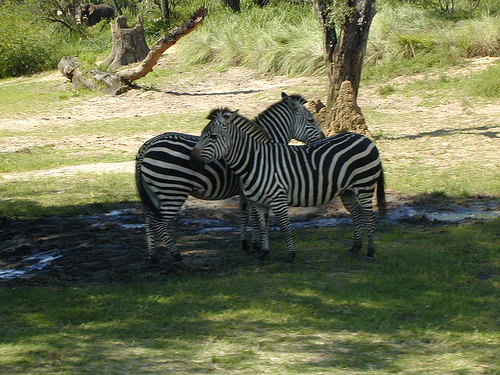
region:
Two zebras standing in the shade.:
[26, 45, 463, 345]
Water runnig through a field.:
[6, 130, 495, 312]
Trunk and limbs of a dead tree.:
[51, 8, 206, 102]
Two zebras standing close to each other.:
[118, 62, 403, 292]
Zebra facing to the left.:
[185, 100, 397, 265]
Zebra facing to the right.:
[135, 82, 322, 261]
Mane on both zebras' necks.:
[190, 91, 285, 176]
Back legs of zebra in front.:
[334, 127, 386, 272]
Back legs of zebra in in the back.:
[132, 148, 186, 277]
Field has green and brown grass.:
[16, 60, 483, 372]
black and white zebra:
[192, 109, 389, 259]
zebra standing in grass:
[131, 94, 324, 272]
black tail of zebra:
[378, 160, 388, 222]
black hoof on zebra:
[368, 249, 375, 258]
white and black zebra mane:
[206, 107, 271, 146]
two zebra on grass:
[135, 90, 390, 265]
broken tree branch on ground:
[48, 9, 205, 92]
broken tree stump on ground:
[107, 15, 150, 62]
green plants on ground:
[2, 3, 78, 75]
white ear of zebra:
[220, 112, 233, 123]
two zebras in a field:
[124, 85, 399, 285]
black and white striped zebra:
[188, 103, 391, 265]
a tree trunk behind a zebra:
[311, 0, 374, 145]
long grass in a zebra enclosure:
[181, 3, 491, 85]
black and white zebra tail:
[131, 151, 165, 222]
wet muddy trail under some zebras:
[1, 198, 498, 285]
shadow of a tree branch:
[122, 70, 287, 99]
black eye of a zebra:
[208, 130, 221, 141]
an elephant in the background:
[73, 3, 118, 35]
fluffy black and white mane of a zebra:
[204, 107, 274, 145]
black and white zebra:
[259, 96, 319, 128]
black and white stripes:
[298, 170, 343, 203]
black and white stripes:
[154, 141, 200, 195]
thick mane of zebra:
[241, 111, 253, 127]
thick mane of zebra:
[254, 99, 284, 116]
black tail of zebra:
[370, 139, 387, 226]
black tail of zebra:
[122, 171, 159, 228]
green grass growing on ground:
[162, 286, 303, 366]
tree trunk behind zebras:
[330, 18, 369, 115]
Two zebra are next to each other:
[130, 88, 392, 270]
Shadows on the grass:
[2, 186, 497, 373]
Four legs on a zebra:
[254, 192, 380, 266]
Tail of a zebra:
[133, 132, 167, 226]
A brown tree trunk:
[320, 15, 367, 122]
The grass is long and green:
[177, 1, 497, 99]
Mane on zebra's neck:
[221, 106, 275, 149]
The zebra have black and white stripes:
[129, 89, 393, 269]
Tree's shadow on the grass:
[129, 77, 260, 101]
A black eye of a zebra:
[204, 130, 223, 146]